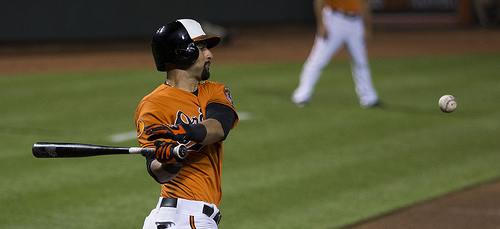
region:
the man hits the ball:
[35, 18, 220, 227]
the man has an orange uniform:
[136, 80, 242, 203]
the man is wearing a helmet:
[151, 19, 220, 71]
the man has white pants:
[139, 197, 226, 227]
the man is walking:
[293, 9, 388, 110]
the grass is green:
[0, 72, 497, 224]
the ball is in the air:
[438, 93, 457, 110]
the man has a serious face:
[178, 45, 213, 80]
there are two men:
[27, 0, 381, 226]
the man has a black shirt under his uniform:
[146, 99, 235, 175]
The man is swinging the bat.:
[43, 22, 263, 225]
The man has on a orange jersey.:
[127, 88, 249, 194]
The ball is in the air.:
[404, 91, 473, 131]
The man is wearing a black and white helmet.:
[139, 12, 246, 84]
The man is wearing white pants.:
[292, 22, 407, 119]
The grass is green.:
[275, 110, 477, 194]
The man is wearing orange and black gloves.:
[150, 125, 224, 142]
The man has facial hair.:
[182, 47, 239, 96]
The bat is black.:
[27, 132, 143, 176]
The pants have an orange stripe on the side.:
[186, 195, 208, 227]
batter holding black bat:
[31, 17, 241, 228]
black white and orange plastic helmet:
[149, 19, 217, 69]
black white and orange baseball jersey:
[131, 83, 237, 205]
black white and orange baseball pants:
[136, 195, 222, 227]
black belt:
[156, 195, 221, 217]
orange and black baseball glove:
[145, 118, 205, 139]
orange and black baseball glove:
[153, 137, 187, 162]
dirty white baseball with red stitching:
[437, 93, 457, 110]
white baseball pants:
[293, 11, 381, 103]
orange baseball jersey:
[328, 1, 363, 16]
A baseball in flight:
[380, 66, 461, 172]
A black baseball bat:
[25, 125, 190, 165]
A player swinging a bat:
[20, 15, 255, 225]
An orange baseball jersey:
[130, 80, 240, 205]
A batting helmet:
[145, 15, 222, 75]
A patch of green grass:
[270, 110, 411, 190]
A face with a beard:
[136, 0, 236, 80]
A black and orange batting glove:
[135, 117, 205, 143]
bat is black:
[33, 137, 190, 164]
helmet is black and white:
[150, 17, 225, 74]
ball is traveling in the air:
[436, 91, 458, 114]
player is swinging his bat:
[28, 14, 238, 227]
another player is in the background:
[288, 0, 388, 110]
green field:
[0, 51, 499, 227]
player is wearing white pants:
[292, 0, 388, 110]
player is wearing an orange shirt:
[136, 76, 241, 211]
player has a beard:
[197, 56, 214, 81]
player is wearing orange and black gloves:
[142, 120, 206, 175]